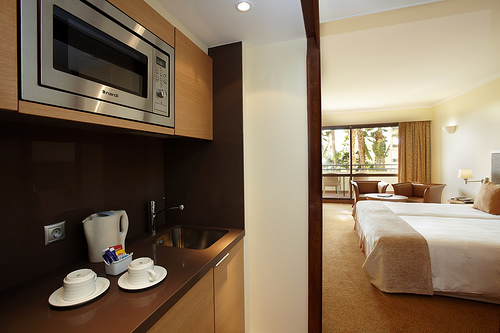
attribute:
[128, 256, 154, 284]
cup — on top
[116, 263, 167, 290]
plate — white, small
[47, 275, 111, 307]
saucer — White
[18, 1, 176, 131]
microwave — silver, built in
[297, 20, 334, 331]
framing — wood 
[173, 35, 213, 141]
cabinet — brown, wooden, kitchen cabinet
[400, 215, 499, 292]
blanket — white 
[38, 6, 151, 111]
door — black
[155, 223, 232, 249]
sink — at the edge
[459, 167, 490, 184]
lamp — with white shade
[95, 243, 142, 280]
caddy — sugar caddy, for the hotel patrons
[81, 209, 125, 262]
white pitcher — ceramic 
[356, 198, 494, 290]
blanket — tan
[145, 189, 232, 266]
sink — hotel room's sink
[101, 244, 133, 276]
holder — ceramic holder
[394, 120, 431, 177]
curtain — long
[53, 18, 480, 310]
room — hotel room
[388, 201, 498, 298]
bedspread — White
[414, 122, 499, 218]
wall — mounted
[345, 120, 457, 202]
drapes — pulled back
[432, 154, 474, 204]
shade — cream